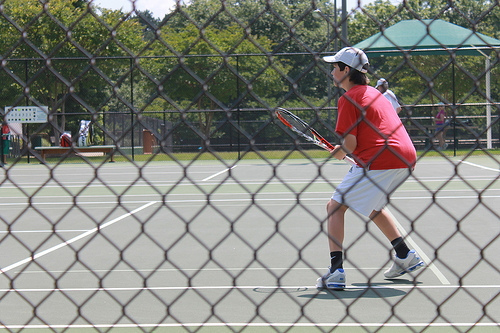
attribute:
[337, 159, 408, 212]
shorts — white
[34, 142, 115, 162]
bench — long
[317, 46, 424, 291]
man — waiting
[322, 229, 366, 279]
sock — black, shin high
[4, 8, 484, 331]
fence — tall, black, chain link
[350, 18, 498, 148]
tent — green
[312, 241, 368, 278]
calf socks — black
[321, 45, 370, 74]
cap — white, for baseball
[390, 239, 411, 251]
sock — black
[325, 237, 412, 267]
socks. — pair, black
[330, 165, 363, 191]
shorts — knee high, white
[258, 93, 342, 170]
racket — red and white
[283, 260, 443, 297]
shoes — pair, white, gray, and light blue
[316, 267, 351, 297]
shoe — for tennis, white, gray, and blue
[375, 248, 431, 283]
shoe — woman's, for tennis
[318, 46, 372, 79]
cap — white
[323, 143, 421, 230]
short — white, woman's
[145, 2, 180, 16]
cloud — small, white